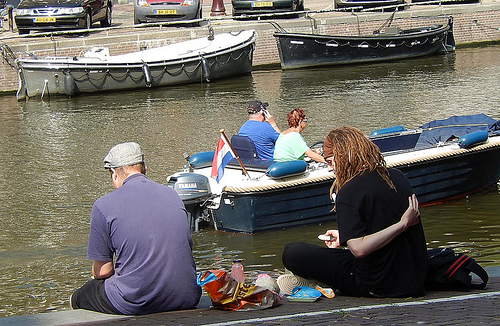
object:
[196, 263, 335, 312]
items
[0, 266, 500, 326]
platform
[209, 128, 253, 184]
flag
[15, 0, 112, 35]
car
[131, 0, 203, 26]
car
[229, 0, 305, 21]
car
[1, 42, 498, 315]
water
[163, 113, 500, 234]
boat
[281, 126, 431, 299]
person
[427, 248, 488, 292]
bag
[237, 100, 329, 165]
people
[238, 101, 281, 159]
person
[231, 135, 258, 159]
backrest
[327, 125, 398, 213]
hair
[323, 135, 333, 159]
band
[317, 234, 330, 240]
something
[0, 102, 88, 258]
sea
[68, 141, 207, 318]
man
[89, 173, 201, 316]
shirt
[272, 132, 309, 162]
shirt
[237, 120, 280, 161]
shirt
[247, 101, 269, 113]
hat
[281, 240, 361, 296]
pants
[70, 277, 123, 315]
pants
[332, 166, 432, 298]
shirt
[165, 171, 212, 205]
motor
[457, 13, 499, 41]
wall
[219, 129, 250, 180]
pole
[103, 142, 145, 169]
cap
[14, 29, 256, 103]
boat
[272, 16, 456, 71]
boat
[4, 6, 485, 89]
dock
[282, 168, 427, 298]
clothing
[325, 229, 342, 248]
right hand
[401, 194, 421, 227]
left hand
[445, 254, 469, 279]
stripe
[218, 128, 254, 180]
flag pole